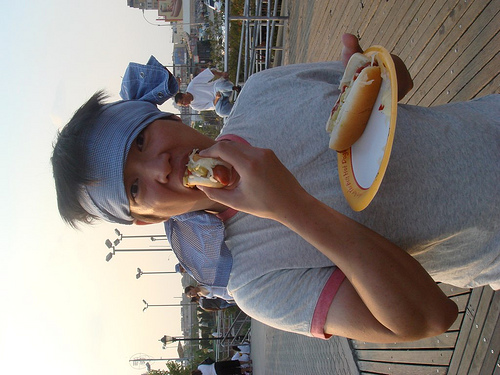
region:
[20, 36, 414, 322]
man eating hot dog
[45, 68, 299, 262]
hot dog being eaten by man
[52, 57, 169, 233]
head band tied on head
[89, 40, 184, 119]
knot on end of head band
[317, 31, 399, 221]
yellow and white plate in hand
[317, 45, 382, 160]
brown and white hot dog bun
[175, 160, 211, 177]
mustard on top of hot dog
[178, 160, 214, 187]
onions on top of hot dog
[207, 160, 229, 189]
tip of hot dog coming out of bun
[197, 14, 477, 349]
grey t-shirt with red trim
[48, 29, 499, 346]
A man in a grey shirt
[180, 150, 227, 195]
A hot dog being eaten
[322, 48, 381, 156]
A hot dog on a plate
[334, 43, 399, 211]
A white and yellow paper plate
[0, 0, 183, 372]
A clear blue sky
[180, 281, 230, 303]
A woman in a white shirt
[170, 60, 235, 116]
A man in a white shirt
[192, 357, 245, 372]
A person in a white shirt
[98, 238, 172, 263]
A tall street light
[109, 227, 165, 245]
A tall street light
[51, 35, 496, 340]
the boy is eating a hotdog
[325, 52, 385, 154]
the boy is holding a hotdog on a plate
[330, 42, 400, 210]
the hotdog is on a paper plate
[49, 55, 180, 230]
the person has a blue bandana on his head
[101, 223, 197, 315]
streetlights are on poles behind the boy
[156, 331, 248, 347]
a black street lamp is on the deck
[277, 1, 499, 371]
the man is standing on wood decking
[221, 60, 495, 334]
the man is wearing a t-shirt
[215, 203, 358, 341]
the t-shirt is trimmed in red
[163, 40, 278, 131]
a man is sitting on a fence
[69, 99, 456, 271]
a man eating burger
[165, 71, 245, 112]
a person sitting in the sidewalk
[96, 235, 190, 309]
electric post with lamp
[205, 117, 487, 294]
a person wearing t-shirt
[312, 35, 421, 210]
a person holding plate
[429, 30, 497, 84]
a person standing in the wooden floor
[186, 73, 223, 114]
a person weating white color t-shirt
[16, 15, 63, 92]
sky with clouds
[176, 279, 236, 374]
lot of persons standing near the steel fencing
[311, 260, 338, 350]
red color border of the t-shirt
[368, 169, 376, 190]
part of a plate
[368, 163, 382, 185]
edge of a plate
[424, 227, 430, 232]
part of a shirt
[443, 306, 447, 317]
part of an elbow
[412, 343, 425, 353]
part of the surface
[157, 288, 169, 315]
part of a pole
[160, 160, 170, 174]
nose of a man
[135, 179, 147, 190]
eye of a man